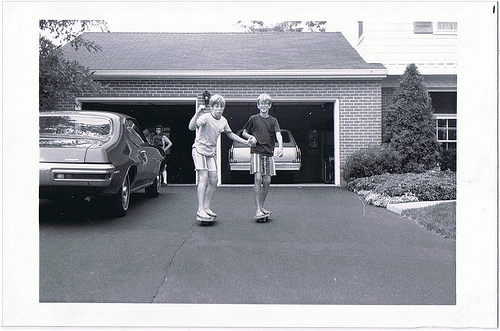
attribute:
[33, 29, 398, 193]
garage — brick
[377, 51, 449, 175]
pine tree — tall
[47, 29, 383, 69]
shingles — black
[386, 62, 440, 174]
leaves — green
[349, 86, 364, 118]
wall — brick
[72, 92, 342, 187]
garage — two door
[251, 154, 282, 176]
shorts — striped